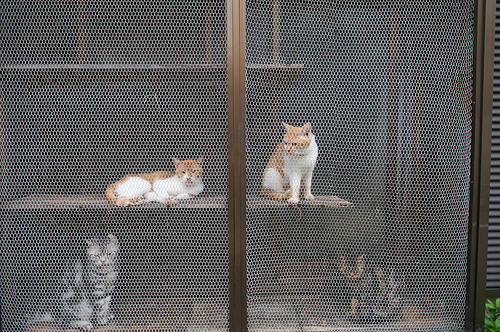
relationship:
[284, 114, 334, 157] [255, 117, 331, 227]
head on cat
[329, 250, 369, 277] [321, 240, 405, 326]
head on cat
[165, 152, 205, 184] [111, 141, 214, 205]
head on cat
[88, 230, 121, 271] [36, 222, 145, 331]
head on cat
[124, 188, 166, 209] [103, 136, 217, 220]
leg on cat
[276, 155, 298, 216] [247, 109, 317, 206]
leg on cat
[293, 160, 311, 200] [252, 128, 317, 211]
leg on cat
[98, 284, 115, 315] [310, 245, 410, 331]
leg on cat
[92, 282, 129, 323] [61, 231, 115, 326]
leg on cat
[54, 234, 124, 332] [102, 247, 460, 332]
cat seated on ground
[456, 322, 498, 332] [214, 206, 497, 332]
bush to  right of cage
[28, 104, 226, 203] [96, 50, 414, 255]
window inside cage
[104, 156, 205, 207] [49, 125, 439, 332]
cat wire enclosing pet cage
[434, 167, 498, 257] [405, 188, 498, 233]
corrugated metal to right of cage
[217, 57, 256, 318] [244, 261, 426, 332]
frame bar between chicken wire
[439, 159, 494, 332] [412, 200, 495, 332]
frame bar to right of chicken wire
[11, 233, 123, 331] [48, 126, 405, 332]
cat in photo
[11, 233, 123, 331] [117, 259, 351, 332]
cat sitting down on ground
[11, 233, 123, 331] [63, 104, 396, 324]
cat in a cage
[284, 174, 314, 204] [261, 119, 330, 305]
front paws of cat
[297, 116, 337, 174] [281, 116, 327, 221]
ear of cat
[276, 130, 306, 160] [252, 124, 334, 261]
eyes of cat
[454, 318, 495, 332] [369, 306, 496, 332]
leaves next to cage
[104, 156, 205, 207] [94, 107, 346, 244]
cat orange and white cat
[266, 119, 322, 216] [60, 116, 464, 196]
cat cat sitting behind grate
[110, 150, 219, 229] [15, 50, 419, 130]
cat cat sitting behind grate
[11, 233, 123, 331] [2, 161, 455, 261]
cat sitting behind gratesmall cat sitting behind grate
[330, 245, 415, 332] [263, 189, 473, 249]
cat sitting behind grate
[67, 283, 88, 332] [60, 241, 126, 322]
gray fur on small cat